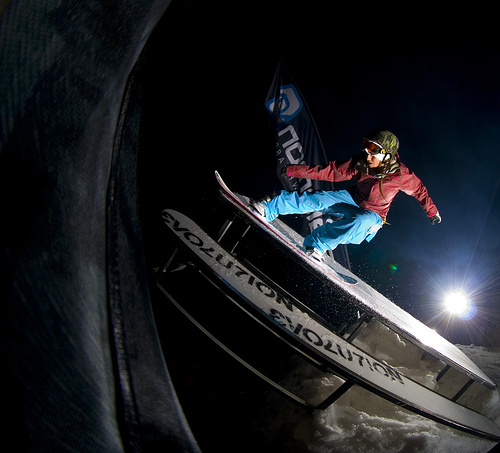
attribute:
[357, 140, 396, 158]
goggles — snow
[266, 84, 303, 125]
logo — white, blue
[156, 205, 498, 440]
bench — white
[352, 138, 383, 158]
goggles — white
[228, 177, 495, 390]
snowboard — white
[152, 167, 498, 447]
bench — white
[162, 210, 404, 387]
lettering — black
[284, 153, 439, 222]
jacket — red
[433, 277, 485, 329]
light — on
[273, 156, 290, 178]
glove — black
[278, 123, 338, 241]
letters — white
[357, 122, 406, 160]
hat — green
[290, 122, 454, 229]
jacket — red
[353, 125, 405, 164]
helmet — green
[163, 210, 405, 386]
writing — black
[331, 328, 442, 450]
ground — snow covered